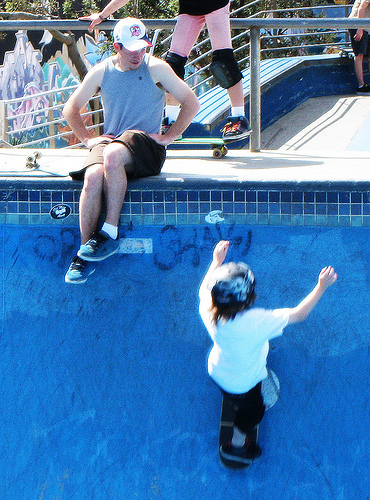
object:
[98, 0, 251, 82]
plethora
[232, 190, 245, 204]
tile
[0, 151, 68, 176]
skateboard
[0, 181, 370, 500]
pool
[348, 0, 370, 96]
person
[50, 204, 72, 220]
sticker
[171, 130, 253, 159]
green skateboard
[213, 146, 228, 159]
yellow wheels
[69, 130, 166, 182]
shorts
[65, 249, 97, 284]
sneaker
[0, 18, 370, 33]
rail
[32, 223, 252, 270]
graffiti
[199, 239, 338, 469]
boy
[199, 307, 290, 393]
white shirt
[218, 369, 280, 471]
skateboard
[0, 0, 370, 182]
skatepark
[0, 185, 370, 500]
wall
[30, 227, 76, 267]
grafitti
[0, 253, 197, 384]
wall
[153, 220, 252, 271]
black graffiti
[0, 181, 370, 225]
tile border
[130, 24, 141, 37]
logo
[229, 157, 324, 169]
shadow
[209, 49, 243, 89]
knee pad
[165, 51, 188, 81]
knee pad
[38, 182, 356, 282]
wall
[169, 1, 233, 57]
pink leggings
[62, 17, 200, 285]
adult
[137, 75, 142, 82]
symbol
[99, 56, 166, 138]
t shirt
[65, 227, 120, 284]
blue shoes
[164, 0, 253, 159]
person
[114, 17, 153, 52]
hat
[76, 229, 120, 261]
sneaker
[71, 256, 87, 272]
laces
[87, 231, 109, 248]
laces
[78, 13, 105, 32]
hand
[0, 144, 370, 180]
ground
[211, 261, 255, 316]
head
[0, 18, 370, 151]
railing